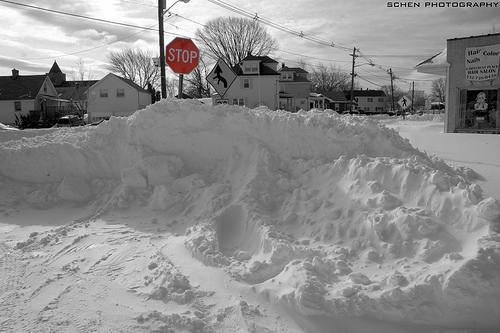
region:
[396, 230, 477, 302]
This is a heap of sand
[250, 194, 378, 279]
This is a heap of sand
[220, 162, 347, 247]
This is a heap of sand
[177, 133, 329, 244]
This is a heap of sand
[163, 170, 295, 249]
This is a heap of sand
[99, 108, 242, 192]
This is a heap of sand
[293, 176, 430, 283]
This is a heap of sand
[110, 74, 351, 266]
This is a heap of sand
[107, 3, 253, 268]
a stop sign beyond a snow bank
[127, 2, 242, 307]
a stop sign behind a snow bank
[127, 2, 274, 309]
stop sign behind a snow bank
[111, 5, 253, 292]
stop sign beyond a snow bank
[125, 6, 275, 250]
stop sign behind a snow mound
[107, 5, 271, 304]
a stop sign behind snow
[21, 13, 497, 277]
a lot that has just been plowed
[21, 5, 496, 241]
a winter cityscape after it has snown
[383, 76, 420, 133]
a sign for a pedestrian crossing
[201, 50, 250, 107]
sign warning of an upcoming left curve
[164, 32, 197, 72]
the top of the stop sign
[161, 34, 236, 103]
the signs behind the snow pile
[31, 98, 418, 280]
the snow pile in front of the signs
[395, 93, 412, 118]
the cross walk sign in the distance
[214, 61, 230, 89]
the arrows on the sign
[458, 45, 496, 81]
the banner on the building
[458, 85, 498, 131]
the window on the storefront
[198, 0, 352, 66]
the power lines hanging in the air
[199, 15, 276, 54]
the tree top behind the roof of the house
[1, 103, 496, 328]
fresh snow on the ground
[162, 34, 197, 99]
stop sign peaking out from the snow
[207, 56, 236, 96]
sign with curved arrow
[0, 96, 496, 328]
large pile of snow burried the sidewalk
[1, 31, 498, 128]
houses in the background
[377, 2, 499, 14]
black text in upper right corner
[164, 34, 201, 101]
stop sign is the only colorful object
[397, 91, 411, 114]
pedestrian walking sign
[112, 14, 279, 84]
these trees are bare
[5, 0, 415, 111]
telephone poles and wires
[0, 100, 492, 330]
a large pile of snow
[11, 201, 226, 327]
car tracks in a snow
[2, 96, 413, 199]
pile of snow almost covers the entire pole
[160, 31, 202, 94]
just the top of the sign sticking out of the snow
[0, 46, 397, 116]
several white houses behind the snow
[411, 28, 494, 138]
a store across from the snow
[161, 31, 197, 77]
stop sign is the only thing in red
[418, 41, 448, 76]
an overhang of the building on the right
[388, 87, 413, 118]
a pedestrian crossing on the upper right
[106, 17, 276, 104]
trees with no leaves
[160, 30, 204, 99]
red and white stop sign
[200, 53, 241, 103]
black arrow on the triangle sign